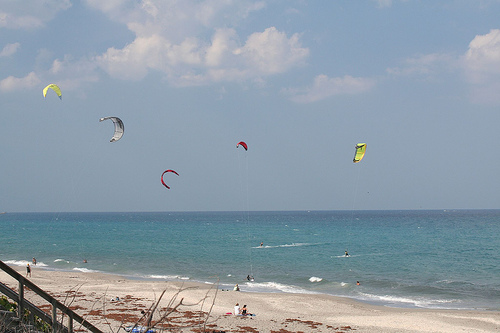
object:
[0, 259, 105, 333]
railing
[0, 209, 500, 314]
ocean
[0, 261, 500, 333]
sand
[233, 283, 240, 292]
person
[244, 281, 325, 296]
waves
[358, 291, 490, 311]
waves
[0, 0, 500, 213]
sky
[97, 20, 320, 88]
clouds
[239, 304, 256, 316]
people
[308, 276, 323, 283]
wave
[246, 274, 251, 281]
person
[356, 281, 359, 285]
person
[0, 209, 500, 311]
water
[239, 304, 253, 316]
couple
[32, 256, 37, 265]
person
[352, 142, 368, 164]
c-kites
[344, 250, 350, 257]
person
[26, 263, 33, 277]
person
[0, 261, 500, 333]
beach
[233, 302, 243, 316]
person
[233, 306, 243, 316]
top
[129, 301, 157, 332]
branch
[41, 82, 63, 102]
c-kite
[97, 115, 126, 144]
c-kite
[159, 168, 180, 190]
c-kite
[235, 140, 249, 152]
c-kite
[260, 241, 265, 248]
people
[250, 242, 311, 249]
waves